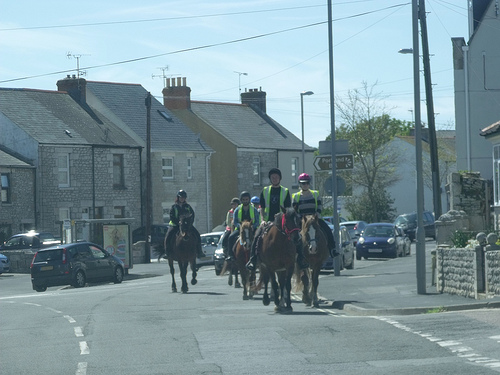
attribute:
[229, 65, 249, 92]
antenna — roof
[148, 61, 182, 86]
antenna — roof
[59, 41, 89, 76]
antenna — roof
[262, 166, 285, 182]
helmet — black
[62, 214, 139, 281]
shelter — bus stop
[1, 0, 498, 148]
sky — clear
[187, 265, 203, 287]
leg — up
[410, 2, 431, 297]
pole — tall, metal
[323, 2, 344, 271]
pole — tall, metal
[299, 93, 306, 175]
pole — tall, metal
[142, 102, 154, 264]
pole — tall, metal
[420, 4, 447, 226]
pole — tall, metal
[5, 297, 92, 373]
line — white, dotted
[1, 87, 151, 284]
building — stone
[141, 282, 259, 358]
street — white